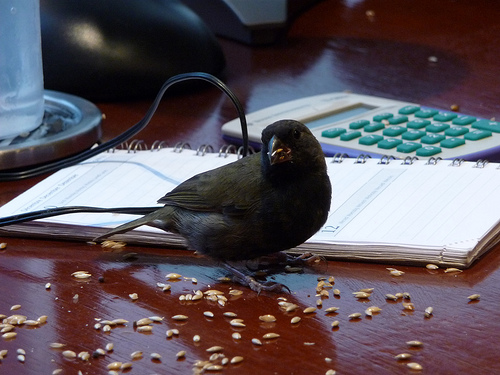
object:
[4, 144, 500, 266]
book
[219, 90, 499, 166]
calculator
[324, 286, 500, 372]
wood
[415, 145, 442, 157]
buttons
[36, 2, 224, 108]
mouse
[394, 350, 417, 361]
pieces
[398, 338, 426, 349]
birdseed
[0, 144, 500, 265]
notebook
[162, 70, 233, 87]
part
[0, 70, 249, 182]
wire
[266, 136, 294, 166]
beak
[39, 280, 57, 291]
food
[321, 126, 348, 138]
button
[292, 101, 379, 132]
screen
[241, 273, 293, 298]
foot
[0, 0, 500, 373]
desk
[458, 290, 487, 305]
seeds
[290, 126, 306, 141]
eye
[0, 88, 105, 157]
coaster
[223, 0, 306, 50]
base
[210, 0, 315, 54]
phone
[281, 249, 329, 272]
claw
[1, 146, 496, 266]
pad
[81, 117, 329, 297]
bird